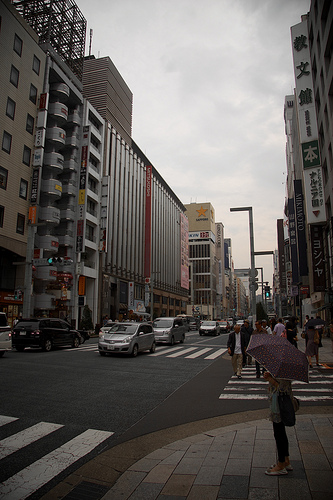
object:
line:
[0, 427, 113, 499]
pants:
[231, 352, 243, 375]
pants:
[271, 421, 290, 460]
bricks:
[160, 472, 196, 495]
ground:
[0, 330, 332, 498]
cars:
[98, 321, 157, 356]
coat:
[227, 329, 245, 356]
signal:
[46, 254, 64, 266]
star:
[195, 201, 210, 217]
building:
[182, 202, 215, 320]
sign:
[78, 275, 86, 293]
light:
[47, 257, 51, 262]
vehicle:
[12, 316, 82, 351]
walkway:
[42, 403, 332, 498]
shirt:
[232, 331, 241, 354]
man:
[227, 322, 245, 378]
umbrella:
[244, 332, 311, 384]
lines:
[183, 345, 213, 359]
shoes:
[264, 460, 287, 475]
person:
[263, 369, 293, 474]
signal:
[265, 287, 269, 298]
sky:
[13, 1, 313, 302]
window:
[207, 259, 210, 274]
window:
[202, 238, 210, 242]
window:
[207, 243, 210, 257]